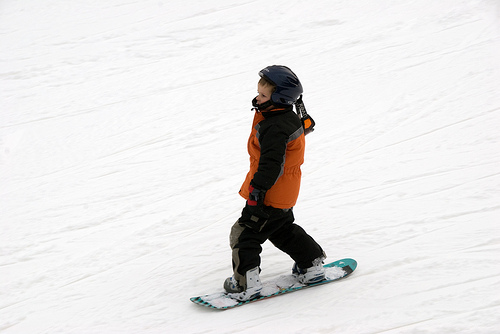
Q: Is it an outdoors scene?
A: Yes, it is outdoors.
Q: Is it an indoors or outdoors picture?
A: It is outdoors.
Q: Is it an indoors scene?
A: No, it is outdoors.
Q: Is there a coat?
A: Yes, there is a coat.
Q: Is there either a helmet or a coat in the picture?
A: Yes, there is a coat.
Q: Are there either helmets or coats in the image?
A: Yes, there is a coat.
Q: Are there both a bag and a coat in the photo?
A: No, there is a coat but no bags.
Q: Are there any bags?
A: No, there are no bags.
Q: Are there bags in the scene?
A: No, there are no bags.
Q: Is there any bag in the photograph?
A: No, there are no bags.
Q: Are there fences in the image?
A: No, there are no fences.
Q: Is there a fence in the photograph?
A: No, there are no fences.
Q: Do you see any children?
A: Yes, there is a child.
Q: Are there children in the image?
A: Yes, there is a child.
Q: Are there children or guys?
A: Yes, there is a child.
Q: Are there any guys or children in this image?
A: Yes, there is a child.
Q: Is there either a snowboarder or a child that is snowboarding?
A: Yes, the child is snowboarding.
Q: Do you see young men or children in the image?
A: Yes, there is a young child.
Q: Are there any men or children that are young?
A: Yes, the child is young.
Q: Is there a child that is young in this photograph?
A: Yes, there is a young child.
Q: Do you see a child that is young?
A: Yes, there is a child that is young.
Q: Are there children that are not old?
A: Yes, there is an young child.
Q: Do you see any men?
A: No, there are no men.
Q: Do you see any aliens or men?
A: No, there are no men or aliens.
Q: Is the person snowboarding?
A: Yes, the kid is snowboarding.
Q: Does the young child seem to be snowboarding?
A: Yes, the child is snowboarding.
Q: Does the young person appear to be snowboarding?
A: Yes, the child is snowboarding.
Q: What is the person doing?
A: The kid is snowboarding.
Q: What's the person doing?
A: The kid is snowboarding.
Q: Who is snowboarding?
A: The child is snowboarding.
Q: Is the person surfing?
A: No, the child is snowboarding.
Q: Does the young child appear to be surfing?
A: No, the kid is snowboarding.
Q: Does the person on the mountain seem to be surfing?
A: No, the kid is snowboarding.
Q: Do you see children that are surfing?
A: No, there is a child but he is snowboarding.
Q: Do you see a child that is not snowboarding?
A: No, there is a child but he is snowboarding.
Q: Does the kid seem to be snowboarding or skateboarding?
A: The kid is snowboarding.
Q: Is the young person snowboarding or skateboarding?
A: The kid is snowboarding.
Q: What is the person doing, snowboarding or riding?
A: The child is snowboarding.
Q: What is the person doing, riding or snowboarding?
A: The child is snowboarding.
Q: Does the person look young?
A: Yes, the kid is young.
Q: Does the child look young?
A: Yes, the child is young.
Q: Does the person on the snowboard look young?
A: Yes, the child is young.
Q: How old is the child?
A: The child is young.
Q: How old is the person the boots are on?
A: The child is young.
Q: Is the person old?
A: No, the child is young.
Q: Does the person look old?
A: No, the kid is young.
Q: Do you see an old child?
A: No, there is a child but he is young.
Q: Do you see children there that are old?
A: No, there is a child but he is young.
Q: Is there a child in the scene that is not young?
A: No, there is a child but he is young.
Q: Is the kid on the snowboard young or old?
A: The kid is young.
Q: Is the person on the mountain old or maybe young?
A: The kid is young.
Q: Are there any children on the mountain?
A: Yes, there is a child on the mountain.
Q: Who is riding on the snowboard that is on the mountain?
A: The child is riding on the snowboard.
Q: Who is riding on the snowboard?
A: The child is riding on the snowboard.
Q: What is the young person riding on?
A: The child is riding on the snowboard.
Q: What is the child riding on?
A: The child is riding on the snowboard.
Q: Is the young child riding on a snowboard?
A: Yes, the kid is riding on a snowboard.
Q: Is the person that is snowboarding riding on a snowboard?
A: Yes, the kid is riding on a snowboard.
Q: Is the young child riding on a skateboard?
A: No, the kid is riding on a snowboard.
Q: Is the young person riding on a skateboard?
A: No, the kid is riding on a snowboard.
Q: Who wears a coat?
A: The child wears a coat.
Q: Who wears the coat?
A: The child wears a coat.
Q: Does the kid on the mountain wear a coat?
A: Yes, the child wears a coat.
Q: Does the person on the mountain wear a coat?
A: Yes, the child wears a coat.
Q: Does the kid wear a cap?
A: No, the kid wears a coat.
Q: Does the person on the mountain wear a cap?
A: No, the kid wears a coat.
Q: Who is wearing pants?
A: The kid is wearing pants.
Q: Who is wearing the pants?
A: The kid is wearing pants.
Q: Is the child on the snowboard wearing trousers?
A: Yes, the kid is wearing trousers.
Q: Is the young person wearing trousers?
A: Yes, the kid is wearing trousers.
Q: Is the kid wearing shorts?
A: No, the kid is wearing trousers.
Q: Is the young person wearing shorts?
A: No, the kid is wearing trousers.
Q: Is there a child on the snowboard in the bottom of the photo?
A: Yes, there is a child on the snow board.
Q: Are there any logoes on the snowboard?
A: No, there is a child on the snowboard.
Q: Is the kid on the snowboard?
A: Yes, the kid is on the snowboard.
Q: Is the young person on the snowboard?
A: Yes, the kid is on the snowboard.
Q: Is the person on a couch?
A: No, the child is on the snowboard.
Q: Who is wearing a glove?
A: The kid is wearing a glove.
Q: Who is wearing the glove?
A: The kid is wearing a glove.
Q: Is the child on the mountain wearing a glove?
A: Yes, the kid is wearing a glove.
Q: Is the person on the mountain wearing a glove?
A: Yes, the kid is wearing a glove.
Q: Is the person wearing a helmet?
A: No, the kid is wearing a glove.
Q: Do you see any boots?
A: Yes, there are boots.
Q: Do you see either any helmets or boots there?
A: Yes, there are boots.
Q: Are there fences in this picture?
A: No, there are no fences.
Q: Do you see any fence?
A: No, there are no fences.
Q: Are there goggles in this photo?
A: Yes, there are goggles.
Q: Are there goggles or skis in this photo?
A: Yes, there are goggles.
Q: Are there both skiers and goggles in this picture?
A: No, there are goggles but no skiers.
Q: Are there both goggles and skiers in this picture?
A: No, there are goggles but no skiers.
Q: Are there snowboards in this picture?
A: Yes, there is a snowboard.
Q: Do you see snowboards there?
A: Yes, there is a snowboard.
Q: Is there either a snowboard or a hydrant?
A: Yes, there is a snowboard.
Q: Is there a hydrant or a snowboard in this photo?
A: Yes, there is a snowboard.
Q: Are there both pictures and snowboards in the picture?
A: No, there is a snowboard but no pictures.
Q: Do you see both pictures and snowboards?
A: No, there is a snowboard but no pictures.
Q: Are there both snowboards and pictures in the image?
A: No, there is a snowboard but no pictures.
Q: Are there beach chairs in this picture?
A: No, there are no beach chairs.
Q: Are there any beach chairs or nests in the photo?
A: No, there are no beach chairs or nests.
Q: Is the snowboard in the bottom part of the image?
A: Yes, the snowboard is in the bottom of the image.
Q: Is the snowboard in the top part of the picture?
A: No, the snowboard is in the bottom of the image.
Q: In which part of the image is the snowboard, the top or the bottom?
A: The snowboard is in the bottom of the image.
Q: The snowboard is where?
A: The snowboard is on the mountain.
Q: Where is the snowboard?
A: The snowboard is on the mountain.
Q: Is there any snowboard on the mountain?
A: Yes, there is a snowboard on the mountain.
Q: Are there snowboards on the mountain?
A: Yes, there is a snowboard on the mountain.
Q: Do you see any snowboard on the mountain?
A: Yes, there is a snowboard on the mountain.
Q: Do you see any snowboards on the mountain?
A: Yes, there is a snowboard on the mountain.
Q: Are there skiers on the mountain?
A: No, there is a snowboard on the mountain.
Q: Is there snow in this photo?
A: Yes, there is snow.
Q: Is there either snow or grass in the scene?
A: Yes, there is snow.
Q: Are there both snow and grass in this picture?
A: No, there is snow but no grass.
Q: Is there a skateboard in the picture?
A: No, there are no skateboards.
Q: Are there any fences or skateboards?
A: No, there are no skateboards or fences.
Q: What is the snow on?
A: The snow is on the snowboard.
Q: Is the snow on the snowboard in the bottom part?
A: Yes, the snow is on the snowboard.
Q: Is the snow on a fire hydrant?
A: No, the snow is on the snowboard.